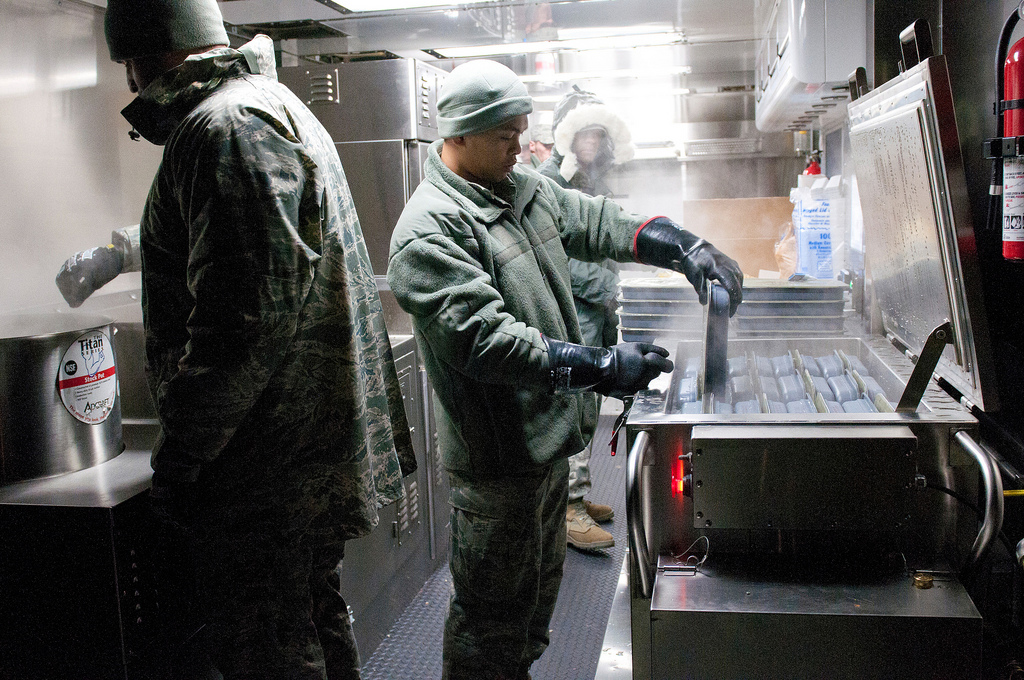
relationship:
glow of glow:
[649, 431, 695, 552] [662, 426, 691, 556]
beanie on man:
[424, 56, 539, 134] [411, 34, 576, 244]